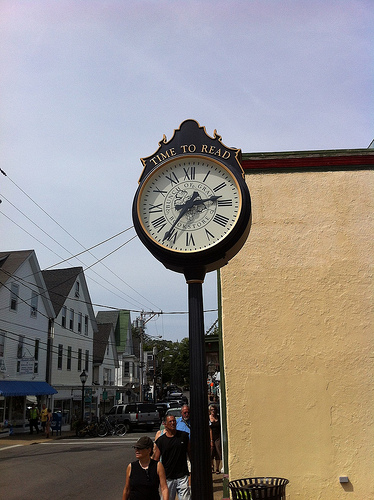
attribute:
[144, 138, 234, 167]
wording — "TIME TO READ"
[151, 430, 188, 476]
shirt — black, sleeveless